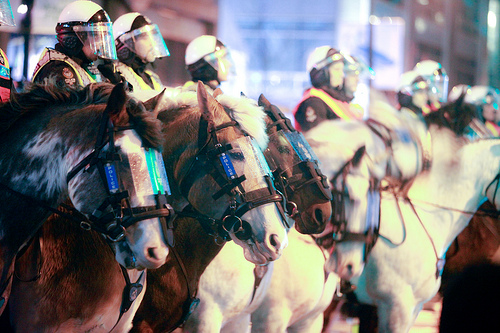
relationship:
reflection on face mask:
[89, 25, 111, 59] [70, 21, 119, 61]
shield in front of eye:
[100, 147, 171, 196] [118, 158, 135, 174]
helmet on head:
[57, 4, 111, 53] [58, 1, 107, 62]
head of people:
[58, 1, 107, 62] [29, 0, 119, 100]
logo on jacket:
[303, 104, 317, 125] [296, 97, 340, 133]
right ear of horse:
[99, 81, 128, 124] [1, 81, 173, 305]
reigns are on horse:
[3, 184, 109, 236] [1, 81, 173, 305]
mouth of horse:
[113, 229, 152, 272] [1, 81, 173, 305]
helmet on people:
[57, 4, 111, 53] [29, 0, 119, 100]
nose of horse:
[141, 239, 172, 269] [1, 81, 173, 305]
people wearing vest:
[29, 0, 119, 100] [30, 48, 96, 87]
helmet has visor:
[57, 4, 111, 53] [70, 21, 119, 61]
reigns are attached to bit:
[3, 184, 109, 236] [104, 220, 127, 242]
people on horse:
[29, 0, 119, 100] [137, 82, 288, 265]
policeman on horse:
[109, 9, 170, 95] [140, 89, 333, 304]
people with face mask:
[29, 0, 119, 100] [70, 21, 119, 61]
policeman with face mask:
[109, 9, 170, 95] [118, 23, 171, 60]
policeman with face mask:
[183, 32, 240, 97] [206, 46, 237, 79]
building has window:
[218, 1, 361, 109] [236, 39, 336, 96]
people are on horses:
[1, 0, 499, 137] [1, 81, 500, 333]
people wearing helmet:
[29, 0, 119, 100] [57, 4, 111, 53]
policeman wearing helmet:
[109, 9, 170, 95] [113, 11, 156, 65]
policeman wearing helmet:
[183, 32, 240, 97] [182, 35, 233, 82]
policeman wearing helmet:
[289, 45, 359, 134] [307, 48, 348, 86]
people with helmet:
[29, 0, 119, 100] [57, 4, 111, 53]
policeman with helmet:
[109, 9, 170, 95] [113, 11, 156, 65]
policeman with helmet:
[183, 32, 240, 97] [182, 35, 233, 82]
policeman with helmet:
[289, 45, 359, 134] [307, 48, 348, 86]